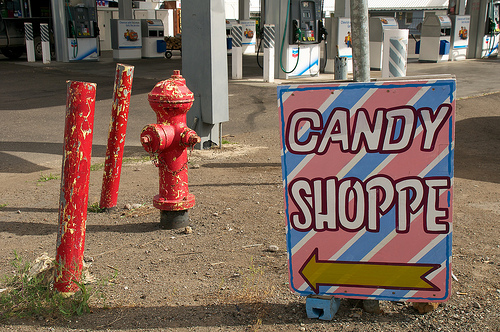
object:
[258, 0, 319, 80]
gas pump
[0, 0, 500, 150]
background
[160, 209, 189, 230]
base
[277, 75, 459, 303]
sign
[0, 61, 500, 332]
ground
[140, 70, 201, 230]
fire hydrant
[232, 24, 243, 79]
pole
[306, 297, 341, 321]
blue brick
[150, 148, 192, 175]
chain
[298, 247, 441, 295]
arrow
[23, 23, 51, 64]
poles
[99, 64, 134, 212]
pole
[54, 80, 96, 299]
pole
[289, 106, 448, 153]
white letters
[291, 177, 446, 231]
white letters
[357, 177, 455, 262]
stripes